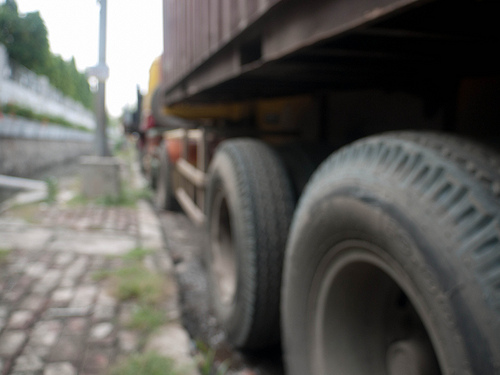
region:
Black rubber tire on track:
[266, 151, 443, 372]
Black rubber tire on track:
[186, 153, 268, 368]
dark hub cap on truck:
[214, 187, 234, 294]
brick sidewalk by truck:
[19, 143, 179, 373]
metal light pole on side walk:
[100, 0, 103, 151]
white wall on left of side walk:
[6, 75, 108, 172]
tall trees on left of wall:
[6, 13, 145, 134]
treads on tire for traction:
[350, 140, 495, 230]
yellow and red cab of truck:
[136, 61, 196, 164]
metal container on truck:
[155, 11, 441, 87]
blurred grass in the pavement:
[86, 241, 179, 330]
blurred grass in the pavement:
[124, 294, 181, 345]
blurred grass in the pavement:
[92, 166, 154, 214]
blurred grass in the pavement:
[86, 193, 145, 218]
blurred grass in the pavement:
[117, 263, 164, 330]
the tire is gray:
[187, 143, 298, 370]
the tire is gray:
[261, 128, 455, 371]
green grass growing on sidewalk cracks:
[117, 160, 156, 368]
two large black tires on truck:
[175, 98, 499, 359]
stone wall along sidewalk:
[4, 66, 86, 176]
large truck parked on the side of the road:
[129, 0, 445, 365]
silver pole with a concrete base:
[69, 0, 155, 198]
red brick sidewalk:
[10, 159, 131, 365]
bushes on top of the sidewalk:
[8, 6, 103, 101]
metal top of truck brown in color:
[155, 1, 277, 103]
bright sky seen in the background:
[31, 8, 164, 99]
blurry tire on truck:
[207, 132, 287, 350]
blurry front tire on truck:
[295, 149, 497, 365]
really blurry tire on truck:
[158, 145, 178, 225]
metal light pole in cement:
[91, 3, 113, 155]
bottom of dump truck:
[168, 5, 487, 109]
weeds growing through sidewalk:
[110, 244, 167, 373]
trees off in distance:
[7, 9, 77, 81]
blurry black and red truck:
[113, 93, 148, 140]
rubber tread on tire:
[347, 125, 486, 228]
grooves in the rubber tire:
[228, 150, 285, 225]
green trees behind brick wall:
[7, 0, 110, 109]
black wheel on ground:
[166, 147, 283, 357]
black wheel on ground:
[276, 131, 497, 372]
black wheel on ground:
[137, 145, 174, 207]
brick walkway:
[0, 163, 185, 365]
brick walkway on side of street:
[0, 125, 168, 370]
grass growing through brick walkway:
[92, 179, 154, 372]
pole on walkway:
[92, 2, 110, 163]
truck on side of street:
[141, 7, 495, 368]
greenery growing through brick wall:
[0, 93, 112, 136]